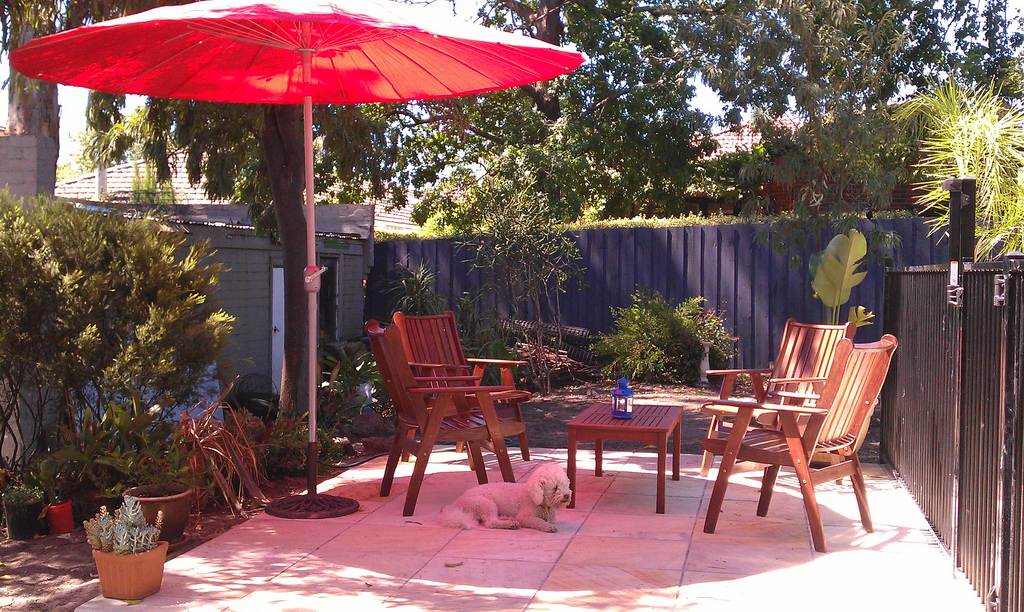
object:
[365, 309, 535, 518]
chair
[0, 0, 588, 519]
umbrella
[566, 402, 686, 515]
table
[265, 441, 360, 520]
umbrella stand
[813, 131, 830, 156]
leaf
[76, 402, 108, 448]
leaf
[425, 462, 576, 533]
dog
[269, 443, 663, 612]
porch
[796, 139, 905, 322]
stem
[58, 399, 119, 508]
stem